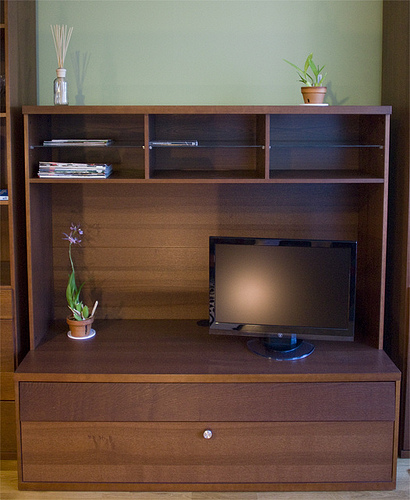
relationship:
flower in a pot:
[61, 225, 101, 322] [64, 316, 94, 336]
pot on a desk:
[64, 316, 94, 336] [15, 105, 400, 493]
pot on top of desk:
[64, 316, 94, 336] [15, 105, 400, 493]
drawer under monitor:
[21, 382, 393, 481] [208, 234, 358, 364]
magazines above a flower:
[39, 159, 114, 180] [61, 225, 101, 322]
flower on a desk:
[61, 225, 101, 322] [15, 105, 400, 493]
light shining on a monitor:
[219, 256, 297, 323] [208, 234, 358, 364]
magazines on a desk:
[39, 159, 114, 180] [15, 105, 400, 493]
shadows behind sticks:
[72, 50, 91, 106] [47, 25, 74, 68]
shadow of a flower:
[86, 271, 126, 332] [61, 225, 101, 322]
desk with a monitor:
[15, 105, 400, 493] [208, 234, 358, 364]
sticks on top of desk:
[47, 25, 74, 68] [15, 105, 400, 493]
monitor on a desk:
[208, 234, 358, 364] [15, 105, 400, 493]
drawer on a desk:
[21, 382, 393, 481] [15, 105, 400, 493]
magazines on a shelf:
[39, 159, 114, 180] [30, 177, 384, 185]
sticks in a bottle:
[47, 25, 74, 68] [54, 69, 69, 105]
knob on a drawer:
[202, 430, 213, 439] [21, 382, 393, 481]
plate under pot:
[68, 330, 95, 339] [64, 316, 94, 336]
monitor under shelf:
[208, 234, 358, 364] [30, 177, 384, 185]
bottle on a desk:
[54, 69, 69, 105] [15, 105, 400, 493]